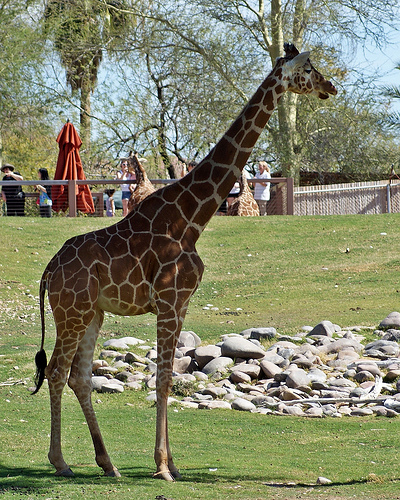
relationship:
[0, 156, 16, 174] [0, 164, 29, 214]
hat on head of man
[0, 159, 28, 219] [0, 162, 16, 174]
man in hat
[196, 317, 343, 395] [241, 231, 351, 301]
rocks on ground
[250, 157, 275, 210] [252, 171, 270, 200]
person wearing shirt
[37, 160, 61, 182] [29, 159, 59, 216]
hair of girl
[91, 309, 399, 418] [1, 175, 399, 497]
rock pile on fenced area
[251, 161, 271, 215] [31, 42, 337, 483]
person looks at giraffe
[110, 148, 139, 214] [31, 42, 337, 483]
person looks at giraffe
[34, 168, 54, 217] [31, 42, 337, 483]
girl looks at giraffe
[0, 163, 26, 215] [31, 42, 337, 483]
man looks at giraffe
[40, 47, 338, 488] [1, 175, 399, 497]
giraffe in fenced area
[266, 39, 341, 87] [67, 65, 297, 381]
head on giraffe